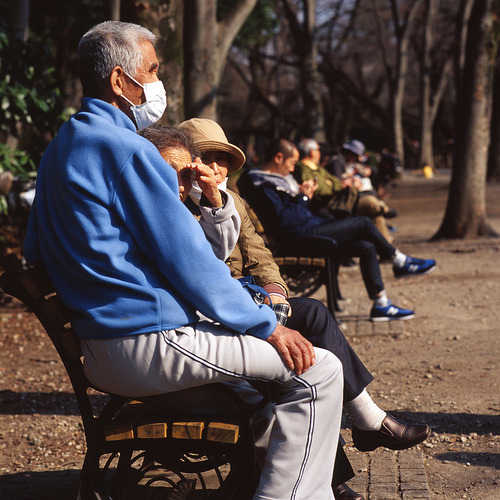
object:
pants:
[274, 295, 374, 404]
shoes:
[338, 474, 366, 500]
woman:
[182, 116, 290, 306]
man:
[24, 19, 350, 498]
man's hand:
[270, 324, 316, 377]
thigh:
[179, 329, 283, 385]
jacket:
[228, 191, 287, 296]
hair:
[78, 21, 158, 95]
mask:
[113, 71, 170, 130]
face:
[134, 40, 162, 115]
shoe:
[353, 408, 432, 452]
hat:
[177, 117, 246, 175]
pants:
[82, 325, 346, 498]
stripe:
[157, 327, 318, 500]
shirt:
[32, 95, 272, 336]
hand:
[183, 160, 218, 199]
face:
[160, 143, 194, 201]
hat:
[342, 140, 365, 156]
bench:
[7, 257, 245, 499]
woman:
[143, 120, 251, 263]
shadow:
[390, 407, 500, 471]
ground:
[357, 182, 500, 498]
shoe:
[392, 256, 438, 280]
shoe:
[369, 303, 417, 323]